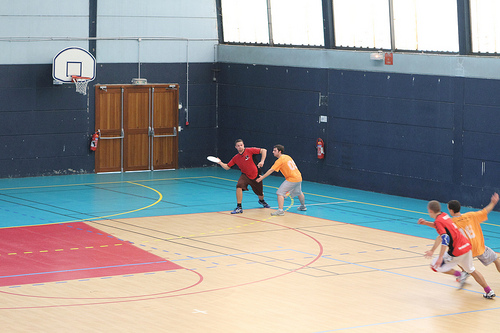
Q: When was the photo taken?
A: Daytime.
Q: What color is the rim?
A: Red.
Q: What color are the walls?
A: Blue.